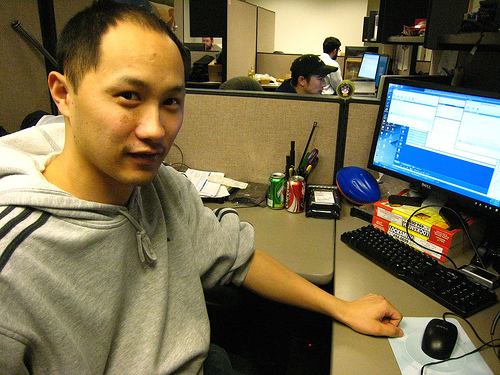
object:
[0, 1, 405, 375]
man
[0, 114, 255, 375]
hoodie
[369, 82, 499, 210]
computer monitor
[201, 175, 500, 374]
table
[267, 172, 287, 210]
soda can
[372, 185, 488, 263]
books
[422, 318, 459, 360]
mouse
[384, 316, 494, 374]
mouse pad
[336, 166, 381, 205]
football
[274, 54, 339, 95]
man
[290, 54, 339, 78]
hat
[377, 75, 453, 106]
computer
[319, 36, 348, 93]
man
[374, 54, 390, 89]
computer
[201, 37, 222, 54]
man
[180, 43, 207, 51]
computer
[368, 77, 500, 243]
computer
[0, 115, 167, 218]
hood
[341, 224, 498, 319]
keyboard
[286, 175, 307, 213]
cup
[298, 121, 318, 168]
pencils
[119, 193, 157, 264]
drawstring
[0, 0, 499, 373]
office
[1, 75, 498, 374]
cubicle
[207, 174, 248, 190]
papers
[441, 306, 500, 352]
wire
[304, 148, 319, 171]
scissor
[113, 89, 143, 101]
eye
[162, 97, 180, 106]
eye